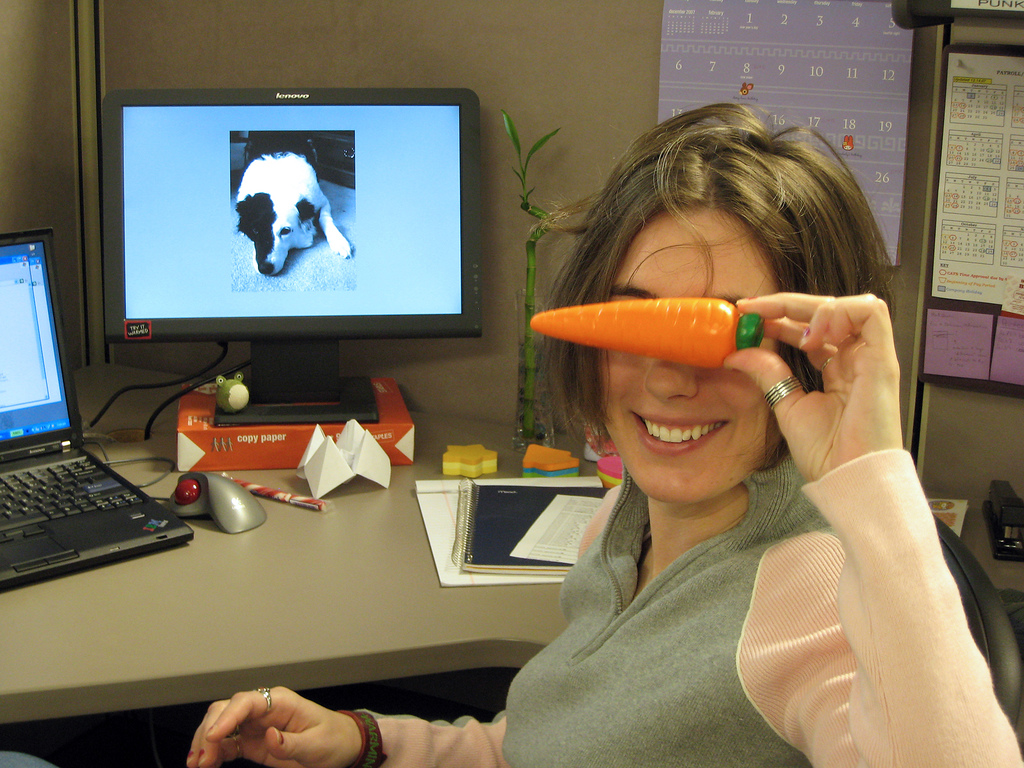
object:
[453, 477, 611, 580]
notebook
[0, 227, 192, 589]
computer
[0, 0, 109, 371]
side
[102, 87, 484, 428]
computer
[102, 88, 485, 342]
monitor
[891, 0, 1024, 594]
wall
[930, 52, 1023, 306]
calendar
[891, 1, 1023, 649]
side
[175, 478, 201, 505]
button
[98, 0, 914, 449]
wall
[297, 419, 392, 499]
paper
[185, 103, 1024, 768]
woman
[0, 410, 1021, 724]
desk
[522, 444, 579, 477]
paper pad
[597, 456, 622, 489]
paper pad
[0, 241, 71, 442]
computer screen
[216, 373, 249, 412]
toy frog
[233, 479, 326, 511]
pen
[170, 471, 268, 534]
computer mouse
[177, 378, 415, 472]
package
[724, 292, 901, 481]
hand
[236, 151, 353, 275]
dog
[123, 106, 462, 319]
computer screen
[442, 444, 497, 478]
note pad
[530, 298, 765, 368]
carrot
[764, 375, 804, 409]
ring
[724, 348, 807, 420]
thumb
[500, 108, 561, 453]
plant